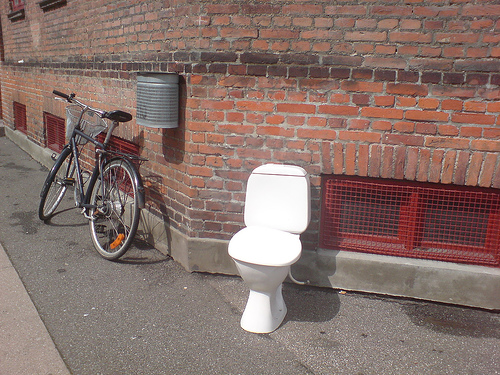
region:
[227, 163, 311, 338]
white toilet on street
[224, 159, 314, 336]
white toilet on gray pavement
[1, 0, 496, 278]
orange brick wall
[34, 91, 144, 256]
big black bicycle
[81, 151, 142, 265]
back black wheel of bicycle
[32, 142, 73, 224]
front black wheel of bicycle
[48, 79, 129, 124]
black and gray handlebar of bicycle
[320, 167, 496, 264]
red grid window on right side of wall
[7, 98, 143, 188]
three small grid windows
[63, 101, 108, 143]
gray bike basket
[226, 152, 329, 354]
white toilet is outdoors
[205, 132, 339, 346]
white toilet next to a wall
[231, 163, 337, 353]
toilet seat is down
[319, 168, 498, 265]
window with red panes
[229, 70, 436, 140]
red bricked wall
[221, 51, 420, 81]
red brick wall stained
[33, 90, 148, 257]
bicycle leaning against wall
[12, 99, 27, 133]
red panes on window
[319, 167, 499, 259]
rectangular shaped window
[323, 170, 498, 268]
small red rectangular window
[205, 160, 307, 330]
This is toilet seat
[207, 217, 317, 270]
This is toilet seat cover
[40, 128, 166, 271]
This is a bycicle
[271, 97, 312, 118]
This is brick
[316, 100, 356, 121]
This is brick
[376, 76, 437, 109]
This is brick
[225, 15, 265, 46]
This is brick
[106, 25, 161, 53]
This is brick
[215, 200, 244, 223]
This is brick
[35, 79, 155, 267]
a bicycle is up against the building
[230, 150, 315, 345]
there is a toilet outside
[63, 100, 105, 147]
the bicycle has a basket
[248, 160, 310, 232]
the toilet tank is white in color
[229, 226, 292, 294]
the toilet bowl is white in color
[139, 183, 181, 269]
a portion of the bikes shadow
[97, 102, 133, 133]
the bicycles seat is black in color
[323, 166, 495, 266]
the window's cover is red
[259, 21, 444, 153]
the building is made up of red bricks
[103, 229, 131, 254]
the light on the bikes tire is orange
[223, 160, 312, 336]
Toilet sitting on the street.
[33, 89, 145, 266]
Bicycle leaning up against the building.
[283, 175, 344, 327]
Shadow of the toilet.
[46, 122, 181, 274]
Shadow of the bike on the ground and wall.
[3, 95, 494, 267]
Red grates on the building.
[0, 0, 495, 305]
Building made of bricks.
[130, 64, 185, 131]
Metal can on the building.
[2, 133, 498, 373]
Sidewalk next to building.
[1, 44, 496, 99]
Darker bricks on the middle of the wall.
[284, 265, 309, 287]
Tube coming out of back of toilet.